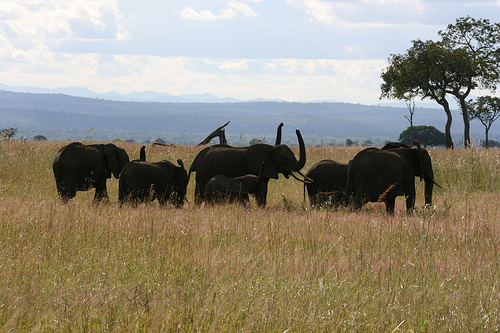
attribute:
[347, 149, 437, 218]
elephant — gray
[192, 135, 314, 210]
elephant — gray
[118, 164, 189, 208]
elephant — gray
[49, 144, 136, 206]
elephant — gray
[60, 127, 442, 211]
elephants — dark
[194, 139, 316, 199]
elephant — gray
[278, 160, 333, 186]
tusks — white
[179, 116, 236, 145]
tree — broken, bent 90 degrees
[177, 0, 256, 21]
cloud — white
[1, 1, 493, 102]
clouds — white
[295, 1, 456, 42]
clouds — white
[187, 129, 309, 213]
elephant — gray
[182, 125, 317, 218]
elephant — baby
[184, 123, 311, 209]
elephant — dark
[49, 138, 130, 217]
elephant — black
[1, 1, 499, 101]
sky — blue